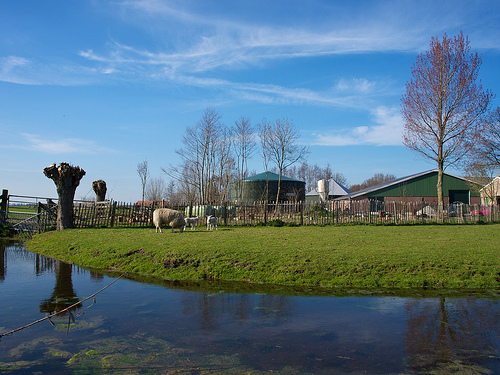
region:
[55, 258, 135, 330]
the water is murky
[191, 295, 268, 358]
the water is murky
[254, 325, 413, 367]
the water is murky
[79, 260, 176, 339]
the water is murky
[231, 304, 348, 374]
the water is murky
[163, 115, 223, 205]
the tree is bare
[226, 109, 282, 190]
the tree is bare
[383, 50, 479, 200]
the tree is bare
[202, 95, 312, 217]
the tree is bare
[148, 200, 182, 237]
brown animal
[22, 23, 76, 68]
white clouds in blue sky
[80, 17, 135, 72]
white clouds in blue sky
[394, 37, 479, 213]
red leaves on tree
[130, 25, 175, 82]
white clouds in blue sky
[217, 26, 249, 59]
white clouds in blue sky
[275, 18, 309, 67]
white clouds in blue sky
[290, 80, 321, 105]
white clouds in blue sky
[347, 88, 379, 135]
white clouds in blue sky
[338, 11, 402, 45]
white clouds in blue sky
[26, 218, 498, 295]
grass across the pond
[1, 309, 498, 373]
moss under the pond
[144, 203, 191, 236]
a sheep on the grass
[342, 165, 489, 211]
a green building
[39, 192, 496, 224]
a fence behind the grass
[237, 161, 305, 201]
a green silo behind the fence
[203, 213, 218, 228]
a lamb near the sheep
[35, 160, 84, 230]
a cut-off tree on the grass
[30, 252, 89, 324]
a shadow in the pond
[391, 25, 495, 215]
a tree behind the fence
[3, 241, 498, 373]
Clear body of water near the grass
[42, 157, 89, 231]
Tree with no leaves or branches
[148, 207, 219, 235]
Group of animals on the grass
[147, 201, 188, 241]
White sheep with alot of fur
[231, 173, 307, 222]
Green building behind the trees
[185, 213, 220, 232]
Pair of white baby animals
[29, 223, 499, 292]
Low cut grassy land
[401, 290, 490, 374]
Reflection of tree in the water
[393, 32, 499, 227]
really tall tree in front of house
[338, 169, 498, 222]
Green and brown house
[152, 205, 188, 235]
Sheep standing on green grass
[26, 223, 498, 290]
Green grass next to body of water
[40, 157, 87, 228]
Tree trunk near sheep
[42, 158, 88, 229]
Tree trunk on green grass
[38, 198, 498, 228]
Wooden fence behind sheep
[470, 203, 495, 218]
Pink car by barn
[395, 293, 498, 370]
Reflection of tree in body of water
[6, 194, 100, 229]
Metal gate behind wooden fence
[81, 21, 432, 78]
Large white wispy cloud in blue sky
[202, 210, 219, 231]
White lamb near sheep